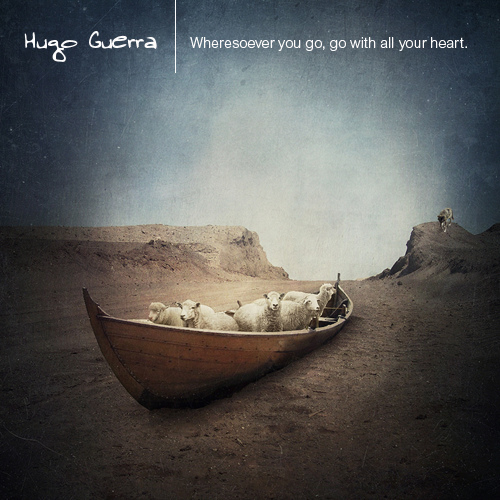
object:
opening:
[268, 224, 393, 280]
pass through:
[290, 227, 373, 282]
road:
[8, 422, 118, 498]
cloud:
[29, 77, 113, 145]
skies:
[262, 150, 405, 214]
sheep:
[148, 300, 184, 331]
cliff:
[401, 217, 471, 274]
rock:
[374, 259, 401, 286]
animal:
[233, 289, 282, 333]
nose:
[272, 303, 279, 307]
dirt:
[291, 460, 325, 499]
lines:
[106, 331, 286, 356]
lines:
[116, 344, 247, 370]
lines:
[125, 357, 222, 379]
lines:
[138, 376, 210, 391]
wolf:
[434, 204, 461, 237]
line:
[169, 0, 181, 74]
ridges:
[403, 258, 463, 291]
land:
[48, 217, 217, 289]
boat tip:
[76, 284, 110, 320]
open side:
[322, 280, 356, 327]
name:
[16, 26, 164, 66]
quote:
[185, 30, 470, 52]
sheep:
[174, 294, 240, 333]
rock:
[406, 225, 463, 263]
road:
[158, 281, 251, 302]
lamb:
[282, 283, 337, 330]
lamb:
[278, 294, 324, 332]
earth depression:
[236, 204, 424, 288]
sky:
[39, 130, 191, 218]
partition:
[4, 227, 498, 495]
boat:
[81, 271, 354, 414]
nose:
[180, 314, 186, 318]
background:
[408, 231, 484, 284]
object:
[434, 206, 455, 232]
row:
[70, 237, 202, 266]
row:
[125, 218, 257, 246]